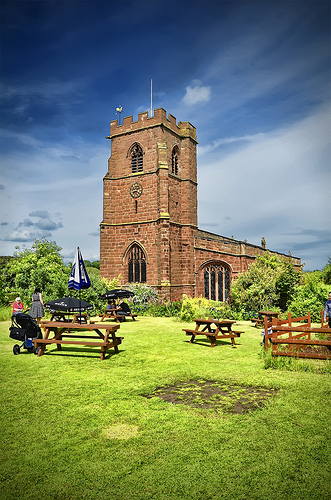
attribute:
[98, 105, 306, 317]
building — brick, red, large, old, attractive, tall, brown, castle-like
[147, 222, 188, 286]
bricks — multicolored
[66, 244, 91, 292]
umbrella — folded, blue, grey, for shade, white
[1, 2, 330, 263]
sky — dark blue, dark, beautiful, blue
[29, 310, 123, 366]
table — light brown, wooden, medium-sized, medium sized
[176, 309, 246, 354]
table — light brown, wooden, medium-sized, medium sized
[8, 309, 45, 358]
stroller — blue, black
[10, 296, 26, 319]
woman — elderly, sitting, wearing sunglasses, wearing jacket, wearing red shirt, white haired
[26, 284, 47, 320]
woman — young, standing, wearing grey dress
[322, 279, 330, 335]
man — standing, looking left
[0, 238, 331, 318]
bushes — bright green, healthy, green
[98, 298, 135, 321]
people — sitting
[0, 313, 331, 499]
grass — green, manicured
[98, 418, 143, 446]
spot — round, circular, white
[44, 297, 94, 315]
umbrella — low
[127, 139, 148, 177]
window — arched, decorative, large, circular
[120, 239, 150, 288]
window — arched, decorative, large, circular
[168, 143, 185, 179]
window — arched, decorative, large, circular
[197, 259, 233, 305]
window — arched, decorative, large, circular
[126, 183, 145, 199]
clock — large, brown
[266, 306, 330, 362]
fence — wooden, three railed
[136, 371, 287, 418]
patch — dirt, square, large, muddy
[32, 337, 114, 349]
bench — large, brown, wooden, picnic-style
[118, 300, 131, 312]
person — wearing black shirt